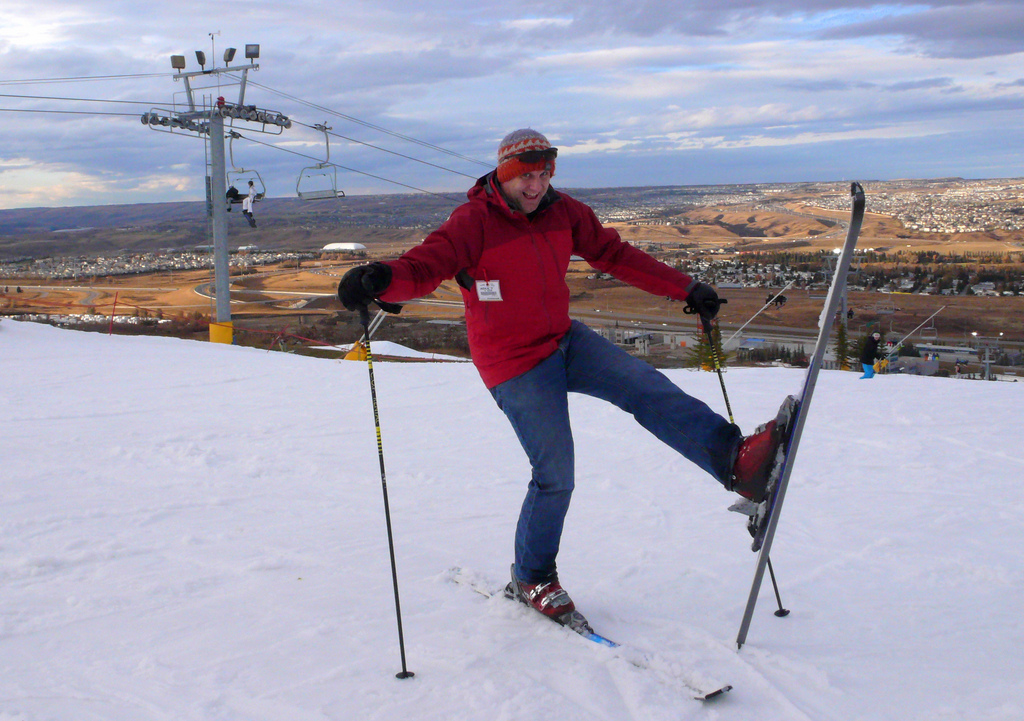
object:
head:
[496, 128, 554, 213]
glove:
[339, 261, 393, 312]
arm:
[570, 199, 699, 303]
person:
[243, 181, 259, 218]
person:
[855, 332, 882, 379]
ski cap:
[498, 126, 556, 181]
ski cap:
[871, 331, 880, 338]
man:
[337, 129, 802, 620]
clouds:
[0, 0, 1024, 209]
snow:
[0, 317, 1024, 721]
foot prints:
[361, 180, 865, 679]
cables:
[0, 31, 498, 206]